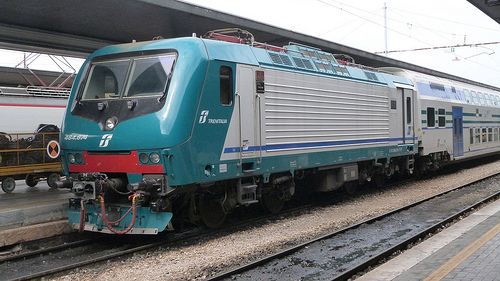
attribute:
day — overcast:
[89, 6, 475, 61]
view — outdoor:
[22, 24, 485, 248]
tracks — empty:
[90, 215, 403, 280]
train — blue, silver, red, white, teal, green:
[100, 40, 450, 179]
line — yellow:
[413, 208, 499, 271]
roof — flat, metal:
[197, 1, 498, 66]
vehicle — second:
[10, 76, 58, 156]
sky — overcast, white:
[343, 13, 499, 58]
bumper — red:
[68, 151, 169, 179]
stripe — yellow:
[462, 235, 491, 262]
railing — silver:
[238, 97, 273, 169]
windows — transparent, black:
[76, 65, 162, 106]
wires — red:
[85, 199, 145, 235]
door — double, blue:
[452, 84, 477, 161]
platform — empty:
[388, 206, 499, 280]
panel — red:
[62, 154, 152, 176]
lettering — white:
[195, 108, 233, 127]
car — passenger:
[430, 83, 490, 164]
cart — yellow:
[6, 136, 72, 171]